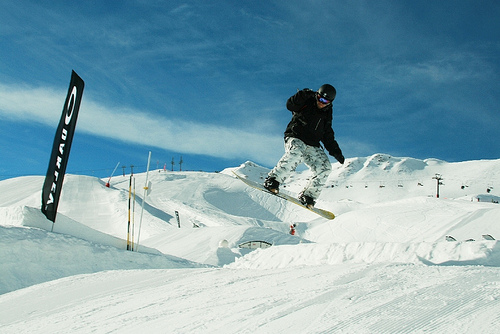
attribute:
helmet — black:
[317, 78, 342, 108]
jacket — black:
[282, 89, 344, 166]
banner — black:
[34, 64, 91, 226]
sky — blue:
[3, 2, 498, 154]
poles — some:
[118, 157, 153, 257]